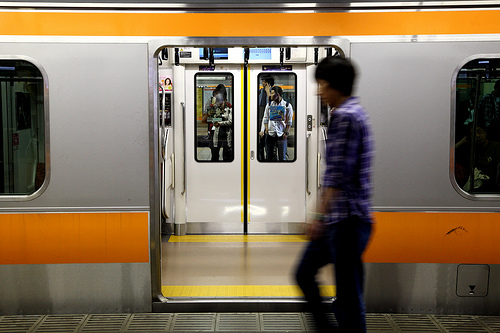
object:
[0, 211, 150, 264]
stripe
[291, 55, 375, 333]
man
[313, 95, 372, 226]
shirt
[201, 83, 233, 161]
person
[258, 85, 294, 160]
person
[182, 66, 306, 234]
door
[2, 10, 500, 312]
train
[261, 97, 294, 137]
shirt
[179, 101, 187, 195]
handle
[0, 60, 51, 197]
window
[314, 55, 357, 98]
hair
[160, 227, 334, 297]
floor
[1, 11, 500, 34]
stripe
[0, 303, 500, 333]
pavement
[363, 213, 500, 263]
stripe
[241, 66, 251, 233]
stripe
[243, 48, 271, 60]
ad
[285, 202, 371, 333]
pants